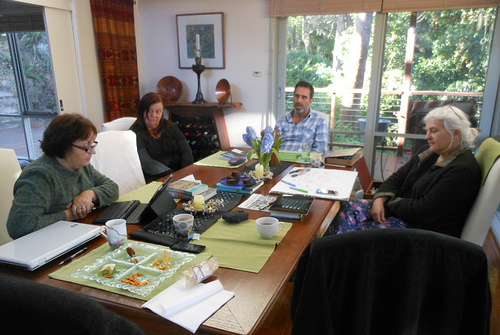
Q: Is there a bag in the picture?
A: No, there are no bags.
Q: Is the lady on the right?
A: Yes, the lady is on the right of the image.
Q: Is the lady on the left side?
A: No, the lady is on the right of the image.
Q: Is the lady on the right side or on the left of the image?
A: The lady is on the right of the image.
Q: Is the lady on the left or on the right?
A: The lady is on the right of the image.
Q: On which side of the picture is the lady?
A: The lady is on the right of the image.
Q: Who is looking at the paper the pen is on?
A: The lady is looking at the paper.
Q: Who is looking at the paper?
A: The lady is looking at the paper.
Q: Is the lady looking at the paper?
A: Yes, the lady is looking at the paper.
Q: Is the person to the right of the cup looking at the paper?
A: Yes, the lady is looking at the paper.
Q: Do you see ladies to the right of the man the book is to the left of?
A: Yes, there is a lady to the right of the man.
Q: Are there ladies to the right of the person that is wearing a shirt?
A: Yes, there is a lady to the right of the man.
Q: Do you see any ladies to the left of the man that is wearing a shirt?
A: No, the lady is to the right of the man.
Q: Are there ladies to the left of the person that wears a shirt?
A: No, the lady is to the right of the man.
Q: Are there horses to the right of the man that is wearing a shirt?
A: No, there is a lady to the right of the man.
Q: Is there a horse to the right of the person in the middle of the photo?
A: No, there is a lady to the right of the man.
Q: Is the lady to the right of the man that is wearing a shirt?
A: Yes, the lady is to the right of the man.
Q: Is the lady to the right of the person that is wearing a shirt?
A: Yes, the lady is to the right of the man.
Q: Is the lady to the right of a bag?
A: No, the lady is to the right of the man.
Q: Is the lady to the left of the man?
A: No, the lady is to the right of the man.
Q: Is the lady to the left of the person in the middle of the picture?
A: No, the lady is to the right of the man.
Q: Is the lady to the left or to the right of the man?
A: The lady is to the right of the man.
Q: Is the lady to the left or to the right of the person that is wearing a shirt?
A: The lady is to the right of the man.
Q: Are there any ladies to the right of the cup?
A: Yes, there is a lady to the right of the cup.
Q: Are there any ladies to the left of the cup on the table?
A: No, the lady is to the right of the cup.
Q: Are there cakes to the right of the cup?
A: No, there is a lady to the right of the cup.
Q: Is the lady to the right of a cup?
A: Yes, the lady is to the right of a cup.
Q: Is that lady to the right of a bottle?
A: No, the lady is to the right of a cup.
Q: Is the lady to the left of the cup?
A: No, the lady is to the right of the cup.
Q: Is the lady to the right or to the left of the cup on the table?
A: The lady is to the right of the cup.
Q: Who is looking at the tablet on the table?
A: The lady is looking at the tablet.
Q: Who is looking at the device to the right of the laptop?
A: The lady is looking at the tablet.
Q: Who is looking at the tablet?
A: The lady is looking at the tablet.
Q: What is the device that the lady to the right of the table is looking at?
A: The device is a tablet.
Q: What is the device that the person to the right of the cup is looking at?
A: The device is a tablet.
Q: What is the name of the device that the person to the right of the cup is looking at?
A: The device is a tablet.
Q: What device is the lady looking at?
A: The lady is looking at the tablet.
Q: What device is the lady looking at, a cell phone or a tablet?
A: The lady is looking at a tablet.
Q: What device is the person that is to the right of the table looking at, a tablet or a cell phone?
A: The lady is looking at a tablet.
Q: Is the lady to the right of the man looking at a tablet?
A: Yes, the lady is looking at a tablet.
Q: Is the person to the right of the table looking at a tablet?
A: Yes, the lady is looking at a tablet.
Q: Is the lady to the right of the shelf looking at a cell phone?
A: No, the lady is looking at a tablet.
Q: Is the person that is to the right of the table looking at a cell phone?
A: No, the lady is looking at a tablet.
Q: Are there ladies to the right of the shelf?
A: Yes, there is a lady to the right of the shelf.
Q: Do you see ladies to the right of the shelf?
A: Yes, there is a lady to the right of the shelf.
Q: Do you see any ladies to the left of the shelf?
A: No, the lady is to the right of the shelf.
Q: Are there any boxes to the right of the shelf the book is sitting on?
A: No, there is a lady to the right of the shelf.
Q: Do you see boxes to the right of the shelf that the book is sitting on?
A: No, there is a lady to the right of the shelf.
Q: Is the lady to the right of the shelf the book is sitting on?
A: Yes, the lady is to the right of the shelf.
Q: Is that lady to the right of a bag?
A: No, the lady is to the right of the shelf.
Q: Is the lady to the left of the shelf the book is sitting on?
A: No, the lady is to the right of the shelf.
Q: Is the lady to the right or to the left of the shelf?
A: The lady is to the right of the shelf.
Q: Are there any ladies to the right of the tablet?
A: Yes, there is a lady to the right of the tablet.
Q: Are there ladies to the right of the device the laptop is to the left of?
A: Yes, there is a lady to the right of the tablet.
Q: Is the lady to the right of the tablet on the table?
A: Yes, the lady is to the right of the tablet.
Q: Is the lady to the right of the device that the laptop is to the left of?
A: Yes, the lady is to the right of the tablet.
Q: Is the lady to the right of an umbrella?
A: No, the lady is to the right of the tablet.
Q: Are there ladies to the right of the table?
A: Yes, there is a lady to the right of the table.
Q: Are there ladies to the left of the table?
A: No, the lady is to the right of the table.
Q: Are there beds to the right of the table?
A: No, there is a lady to the right of the table.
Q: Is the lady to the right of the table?
A: Yes, the lady is to the right of the table.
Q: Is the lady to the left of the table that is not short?
A: No, the lady is to the right of the table.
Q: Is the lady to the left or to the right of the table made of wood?
A: The lady is to the right of the table.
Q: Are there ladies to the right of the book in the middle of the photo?
A: Yes, there is a lady to the right of the book.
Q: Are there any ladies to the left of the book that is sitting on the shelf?
A: No, the lady is to the right of the book.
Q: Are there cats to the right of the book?
A: No, there is a lady to the right of the book.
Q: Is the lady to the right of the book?
A: Yes, the lady is to the right of the book.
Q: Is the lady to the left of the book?
A: No, the lady is to the right of the book.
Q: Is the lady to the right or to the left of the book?
A: The lady is to the right of the book.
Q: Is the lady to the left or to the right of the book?
A: The lady is to the right of the book.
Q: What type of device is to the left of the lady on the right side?
A: The device is a tablet.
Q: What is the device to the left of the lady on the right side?
A: The device is a tablet.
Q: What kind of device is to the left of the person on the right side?
A: The device is a tablet.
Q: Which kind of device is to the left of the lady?
A: The device is a tablet.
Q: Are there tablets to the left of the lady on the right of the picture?
A: Yes, there is a tablet to the left of the lady.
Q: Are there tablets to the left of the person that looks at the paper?
A: Yes, there is a tablet to the left of the lady.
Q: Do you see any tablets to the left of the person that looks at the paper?
A: Yes, there is a tablet to the left of the lady.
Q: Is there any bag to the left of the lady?
A: No, there is a tablet to the left of the lady.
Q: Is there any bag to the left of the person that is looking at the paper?
A: No, there is a tablet to the left of the lady.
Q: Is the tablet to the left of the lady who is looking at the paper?
A: Yes, the tablet is to the left of the lady.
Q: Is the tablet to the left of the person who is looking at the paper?
A: Yes, the tablet is to the left of the lady.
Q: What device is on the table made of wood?
A: The device is a tablet.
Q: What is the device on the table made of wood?
A: The device is a tablet.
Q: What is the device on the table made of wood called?
A: The device is a tablet.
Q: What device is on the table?
A: The device is a tablet.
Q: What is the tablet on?
A: The tablet is on the table.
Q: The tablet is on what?
A: The tablet is on the table.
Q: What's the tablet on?
A: The tablet is on the table.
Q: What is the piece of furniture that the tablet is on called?
A: The piece of furniture is a table.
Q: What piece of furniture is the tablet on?
A: The tablet is on the table.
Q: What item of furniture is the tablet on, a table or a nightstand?
A: The tablet is on a table.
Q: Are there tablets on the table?
A: Yes, there is a tablet on the table.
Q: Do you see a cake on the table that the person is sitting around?
A: No, there is a tablet on the table.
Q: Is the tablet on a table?
A: Yes, the tablet is on a table.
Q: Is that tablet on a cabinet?
A: No, the tablet is on a table.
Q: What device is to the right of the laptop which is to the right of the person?
A: The device is a tablet.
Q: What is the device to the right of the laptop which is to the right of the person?
A: The device is a tablet.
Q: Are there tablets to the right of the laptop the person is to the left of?
A: Yes, there is a tablet to the right of the laptop.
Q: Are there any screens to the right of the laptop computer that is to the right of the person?
A: No, there is a tablet to the right of the laptop.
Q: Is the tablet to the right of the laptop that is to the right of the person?
A: Yes, the tablet is to the right of the laptop computer.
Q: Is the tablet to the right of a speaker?
A: No, the tablet is to the right of the laptop computer.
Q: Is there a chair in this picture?
A: Yes, there is a chair.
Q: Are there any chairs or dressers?
A: Yes, there is a chair.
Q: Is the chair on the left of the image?
A: Yes, the chair is on the left of the image.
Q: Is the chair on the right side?
A: No, the chair is on the left of the image.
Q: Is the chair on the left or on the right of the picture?
A: The chair is on the left of the image.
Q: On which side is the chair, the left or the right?
A: The chair is on the left of the image.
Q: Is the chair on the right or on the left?
A: The chair is on the left of the image.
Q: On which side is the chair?
A: The chair is on the left of the image.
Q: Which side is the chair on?
A: The chair is on the left of the image.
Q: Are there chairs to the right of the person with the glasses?
A: Yes, there is a chair to the right of the person.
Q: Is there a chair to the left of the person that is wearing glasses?
A: No, the chair is to the right of the person.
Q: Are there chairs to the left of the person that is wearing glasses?
A: No, the chair is to the right of the person.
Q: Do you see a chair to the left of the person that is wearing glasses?
A: No, the chair is to the right of the person.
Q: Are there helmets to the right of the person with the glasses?
A: No, there is a chair to the right of the person.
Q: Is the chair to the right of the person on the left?
A: Yes, the chair is to the right of the person.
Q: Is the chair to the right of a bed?
A: No, the chair is to the right of the person.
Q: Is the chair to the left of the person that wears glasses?
A: No, the chair is to the right of the person.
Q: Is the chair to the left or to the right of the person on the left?
A: The chair is to the right of the person.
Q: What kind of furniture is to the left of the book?
A: The piece of furniture is a chair.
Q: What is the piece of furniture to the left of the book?
A: The piece of furniture is a chair.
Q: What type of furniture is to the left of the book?
A: The piece of furniture is a chair.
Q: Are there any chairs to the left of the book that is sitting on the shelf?
A: Yes, there is a chair to the left of the book.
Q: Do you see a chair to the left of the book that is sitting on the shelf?
A: Yes, there is a chair to the left of the book.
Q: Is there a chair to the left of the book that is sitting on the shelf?
A: Yes, there is a chair to the left of the book.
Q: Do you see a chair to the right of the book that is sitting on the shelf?
A: No, the chair is to the left of the book.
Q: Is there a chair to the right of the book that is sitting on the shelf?
A: No, the chair is to the left of the book.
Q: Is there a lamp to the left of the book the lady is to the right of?
A: No, there is a chair to the left of the book.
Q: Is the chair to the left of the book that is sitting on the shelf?
A: Yes, the chair is to the left of the book.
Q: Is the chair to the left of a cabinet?
A: No, the chair is to the left of the book.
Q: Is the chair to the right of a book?
A: No, the chair is to the left of a book.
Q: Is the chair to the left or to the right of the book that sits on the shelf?
A: The chair is to the left of the book.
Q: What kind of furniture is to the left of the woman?
A: The piece of furniture is a chair.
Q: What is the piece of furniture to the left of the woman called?
A: The piece of furniture is a chair.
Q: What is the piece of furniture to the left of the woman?
A: The piece of furniture is a chair.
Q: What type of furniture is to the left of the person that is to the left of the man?
A: The piece of furniture is a chair.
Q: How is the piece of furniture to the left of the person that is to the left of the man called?
A: The piece of furniture is a chair.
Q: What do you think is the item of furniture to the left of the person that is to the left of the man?
A: The piece of furniture is a chair.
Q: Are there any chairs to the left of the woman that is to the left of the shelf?
A: Yes, there is a chair to the left of the woman.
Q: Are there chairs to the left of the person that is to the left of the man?
A: Yes, there is a chair to the left of the woman.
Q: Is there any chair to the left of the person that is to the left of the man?
A: Yes, there is a chair to the left of the woman.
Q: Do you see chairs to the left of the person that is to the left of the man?
A: Yes, there is a chair to the left of the woman.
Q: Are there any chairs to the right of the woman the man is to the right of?
A: No, the chair is to the left of the woman.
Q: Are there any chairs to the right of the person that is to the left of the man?
A: No, the chair is to the left of the woman.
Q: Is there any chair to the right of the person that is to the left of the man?
A: No, the chair is to the left of the woman.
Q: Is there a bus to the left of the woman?
A: No, there is a chair to the left of the woman.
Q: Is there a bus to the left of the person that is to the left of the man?
A: No, there is a chair to the left of the woman.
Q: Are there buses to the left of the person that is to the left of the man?
A: No, there is a chair to the left of the woman.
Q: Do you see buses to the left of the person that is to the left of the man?
A: No, there is a chair to the left of the woman.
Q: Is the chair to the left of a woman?
A: Yes, the chair is to the left of a woman.